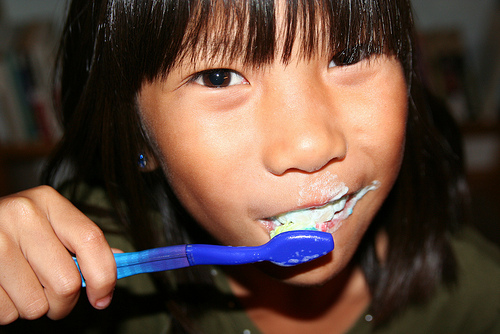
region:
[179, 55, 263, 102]
the eye of a girl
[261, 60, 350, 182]
the nose of a girl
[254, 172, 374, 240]
the mouth of a girl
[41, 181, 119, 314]
the finger of a girl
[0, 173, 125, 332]
the hand of a girl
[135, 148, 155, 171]
a blue earring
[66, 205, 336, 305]
a blue toothbrush in the girl's hand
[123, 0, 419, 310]
the head of a girl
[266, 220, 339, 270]
the head of the toothbrush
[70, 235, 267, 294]
the handle of the toothbrush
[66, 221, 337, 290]
The blue toothbrush held by the girl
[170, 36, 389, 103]
The eyes of the girl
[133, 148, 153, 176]
The blue earing of the girl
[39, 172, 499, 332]
The girls green shirt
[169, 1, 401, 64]
The bangs of the girl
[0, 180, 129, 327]
The Hand holding the toothbrush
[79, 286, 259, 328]
The shadow of the toothbrush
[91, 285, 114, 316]
The only fingernail shown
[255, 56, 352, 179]
The nose of the girl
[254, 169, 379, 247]
The toothpaste around the girl's mouth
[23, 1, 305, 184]
girl has dark hair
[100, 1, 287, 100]
girl has thin hair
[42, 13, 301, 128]
girl has straight hair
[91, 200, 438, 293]
girl is holding toothbrush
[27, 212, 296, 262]
toothbrush is dark blue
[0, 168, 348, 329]
girl holds brush in right hand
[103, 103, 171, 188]
girl is wearing earring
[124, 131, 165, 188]
earring in right ear is blue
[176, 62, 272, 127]
girl has brown eyes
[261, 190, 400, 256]
toothbrush bristles are yellow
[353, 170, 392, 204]
toothpaste on girl's cheek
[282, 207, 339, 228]
toothpaste on girl's teeth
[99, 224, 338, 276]
toothbrush in girl's hand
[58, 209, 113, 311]
fingers around the brush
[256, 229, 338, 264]
head of the brush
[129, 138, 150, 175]
ear ring on the girl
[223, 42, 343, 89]
hair on girl's forehead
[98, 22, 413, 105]
banges on the girl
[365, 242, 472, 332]
hair on girls shoulder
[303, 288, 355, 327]
shadow of the girl's chin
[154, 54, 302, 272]
a girl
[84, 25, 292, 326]
a girl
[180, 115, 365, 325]
a girl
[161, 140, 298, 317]
a girl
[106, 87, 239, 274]
a girl